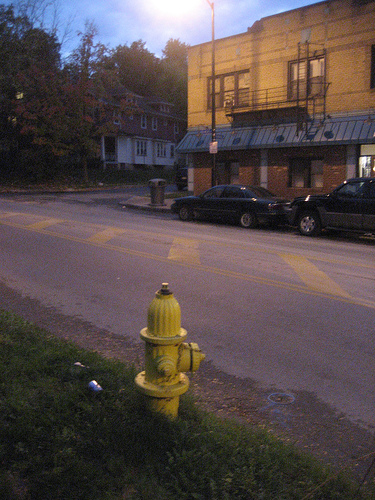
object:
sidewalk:
[118, 184, 187, 216]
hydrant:
[134, 275, 206, 425]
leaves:
[0, 355, 31, 392]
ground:
[0, 171, 373, 500]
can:
[148, 178, 166, 210]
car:
[288, 178, 374, 236]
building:
[174, 1, 374, 206]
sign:
[209, 140, 219, 155]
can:
[89, 377, 102, 394]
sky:
[121, 14, 151, 35]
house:
[96, 93, 189, 171]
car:
[170, 178, 291, 231]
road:
[0, 204, 374, 486]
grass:
[0, 309, 373, 497]